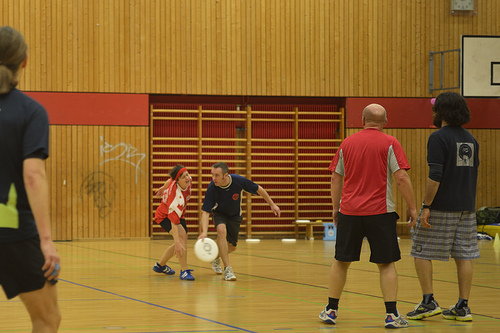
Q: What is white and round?
A: Frisbee.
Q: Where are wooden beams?
A: On the wall.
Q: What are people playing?
A: Frisbee.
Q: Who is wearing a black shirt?
A: Man on the right.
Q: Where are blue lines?
A: On the floor.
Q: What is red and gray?
A: Man's shirt.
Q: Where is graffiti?
A: On the wall.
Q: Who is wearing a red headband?
A: The girl in red and white.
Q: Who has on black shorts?
A: Man wearing red and gray shirt.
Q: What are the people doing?
A: Playing frisbee.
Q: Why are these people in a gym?
A: Playing frisbee.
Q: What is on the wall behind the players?
A: Graffiti.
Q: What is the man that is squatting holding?
A: Frisbee.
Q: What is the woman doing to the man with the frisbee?
A: Blocking.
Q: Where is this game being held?
A: In gym.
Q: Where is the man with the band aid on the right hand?
A: Far left.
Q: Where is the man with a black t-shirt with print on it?
A: Far right.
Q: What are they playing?
A: Games.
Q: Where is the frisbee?
A: In the guys hand.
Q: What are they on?
A: Court.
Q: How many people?
A: 5.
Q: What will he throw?
A: Frisbee.